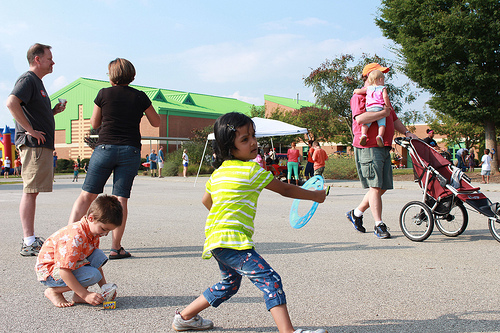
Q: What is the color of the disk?
A: Blue.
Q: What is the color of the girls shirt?
A: Yellow.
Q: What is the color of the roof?
A: Green.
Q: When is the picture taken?
A: Daytime.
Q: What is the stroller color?
A: Red.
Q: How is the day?
A: Sunny.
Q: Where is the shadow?
A: In the ground.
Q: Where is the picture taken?
A: At a park.